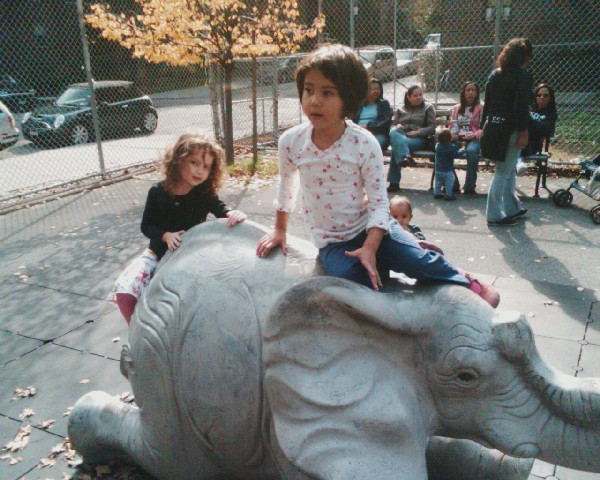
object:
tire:
[69, 125, 88, 145]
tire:
[139, 105, 157, 136]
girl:
[114, 132, 244, 315]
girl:
[254, 44, 501, 303]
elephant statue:
[68, 214, 596, 477]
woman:
[441, 65, 479, 193]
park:
[0, 4, 599, 477]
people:
[480, 27, 538, 223]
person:
[520, 78, 558, 166]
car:
[354, 42, 396, 78]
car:
[397, 42, 433, 78]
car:
[24, 76, 156, 146]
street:
[0, 16, 164, 201]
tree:
[216, 0, 243, 163]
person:
[353, 77, 389, 153]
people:
[389, 80, 428, 195]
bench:
[388, 143, 572, 175]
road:
[0, 135, 150, 189]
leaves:
[79, 5, 105, 27]